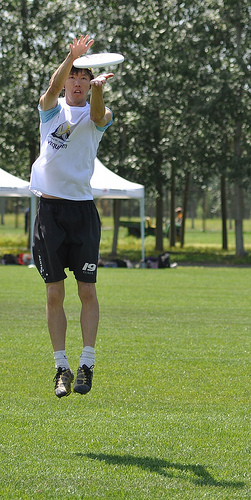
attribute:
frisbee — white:
[72, 47, 123, 66]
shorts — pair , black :
[22, 193, 119, 307]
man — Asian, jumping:
[28, 32, 114, 398]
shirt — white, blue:
[28, 98, 110, 200]